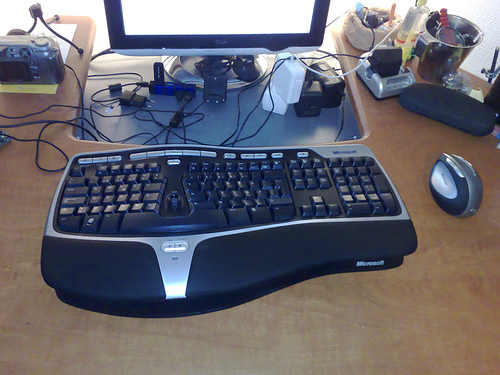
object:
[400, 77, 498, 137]
case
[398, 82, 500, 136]
eye glasses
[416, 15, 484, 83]
cup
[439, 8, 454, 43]
supplies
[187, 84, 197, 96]
slots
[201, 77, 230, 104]
outlet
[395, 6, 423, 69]
ink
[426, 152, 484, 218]
mouse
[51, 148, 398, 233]
keyboard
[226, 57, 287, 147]
cords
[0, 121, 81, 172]
cables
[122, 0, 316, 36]
monitor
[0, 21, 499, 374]
desk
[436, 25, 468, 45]
trinkets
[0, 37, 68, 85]
camera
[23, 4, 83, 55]
tripod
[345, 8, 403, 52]
bowl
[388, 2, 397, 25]
items